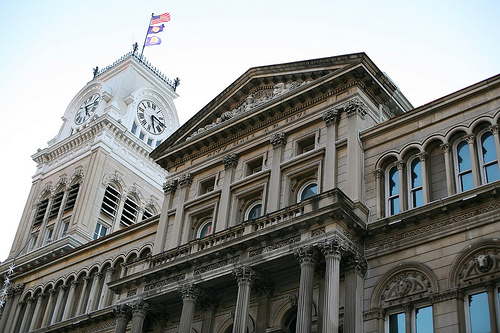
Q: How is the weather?
A: It is clear.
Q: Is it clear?
A: Yes, it is clear.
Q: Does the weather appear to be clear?
A: Yes, it is clear.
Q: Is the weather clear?
A: Yes, it is clear.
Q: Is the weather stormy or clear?
A: It is clear.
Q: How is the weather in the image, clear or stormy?
A: It is clear.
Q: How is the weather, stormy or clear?
A: It is clear.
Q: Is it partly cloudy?
A: No, it is clear.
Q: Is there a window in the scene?
A: Yes, there is a window.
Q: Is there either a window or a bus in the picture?
A: Yes, there is a window.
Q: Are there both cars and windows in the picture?
A: No, there is a window but no cars.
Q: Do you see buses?
A: No, there are no buses.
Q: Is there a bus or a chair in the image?
A: No, there are no buses or chairs.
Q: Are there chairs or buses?
A: No, there are no buses or chairs.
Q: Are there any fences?
A: No, there are no fences.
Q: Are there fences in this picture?
A: No, there are no fences.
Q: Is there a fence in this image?
A: No, there are no fences.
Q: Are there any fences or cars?
A: No, there are no fences or cars.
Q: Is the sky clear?
A: Yes, the sky is clear.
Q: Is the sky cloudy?
A: No, the sky is clear.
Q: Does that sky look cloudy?
A: No, the sky is clear.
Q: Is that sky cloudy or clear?
A: The sky is clear.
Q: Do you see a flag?
A: Yes, there is a flag.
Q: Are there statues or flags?
A: Yes, there is a flag.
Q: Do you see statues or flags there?
A: Yes, there is a flag.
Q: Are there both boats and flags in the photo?
A: No, there is a flag but no boats.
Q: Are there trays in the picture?
A: No, there are no trays.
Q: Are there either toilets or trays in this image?
A: No, there are no trays or toilets.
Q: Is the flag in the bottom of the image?
A: No, the flag is in the top of the image.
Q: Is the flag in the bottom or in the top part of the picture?
A: The flag is in the top of the image.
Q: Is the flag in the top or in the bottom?
A: The flag is in the top of the image.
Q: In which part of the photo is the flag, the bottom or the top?
A: The flag is in the top of the image.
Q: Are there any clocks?
A: Yes, there is a clock.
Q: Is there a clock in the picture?
A: Yes, there is a clock.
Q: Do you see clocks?
A: Yes, there is a clock.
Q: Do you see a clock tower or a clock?
A: Yes, there is a clock.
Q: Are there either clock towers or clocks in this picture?
A: Yes, there is a clock.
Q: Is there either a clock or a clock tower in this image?
A: Yes, there is a clock.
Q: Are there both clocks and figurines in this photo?
A: No, there is a clock but no figurines.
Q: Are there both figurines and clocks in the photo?
A: No, there is a clock but no figurines.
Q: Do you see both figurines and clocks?
A: No, there is a clock but no figurines.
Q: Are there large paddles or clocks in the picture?
A: Yes, there is a large clock.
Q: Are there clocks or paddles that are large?
A: Yes, the clock is large.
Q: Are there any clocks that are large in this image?
A: Yes, there is a large clock.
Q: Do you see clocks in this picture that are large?
A: Yes, there is a clock that is large.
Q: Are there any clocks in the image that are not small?
A: Yes, there is a large clock.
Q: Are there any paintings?
A: No, there are no paintings.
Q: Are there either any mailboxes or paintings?
A: No, there are no paintings or mailboxes.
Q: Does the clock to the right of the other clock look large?
A: Yes, the clock is large.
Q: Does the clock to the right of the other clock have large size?
A: Yes, the clock is large.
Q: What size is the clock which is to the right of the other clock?
A: The clock is large.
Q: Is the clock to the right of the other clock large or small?
A: The clock is large.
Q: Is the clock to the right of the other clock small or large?
A: The clock is large.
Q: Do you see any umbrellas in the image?
A: No, there are no umbrellas.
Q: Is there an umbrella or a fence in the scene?
A: No, there are no umbrellas or fences.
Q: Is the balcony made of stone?
A: Yes, the balcony is made of stone.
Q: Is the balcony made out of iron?
A: No, the balcony is made of stone.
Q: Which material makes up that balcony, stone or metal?
A: The balcony is made of stone.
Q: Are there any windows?
A: Yes, there is a window.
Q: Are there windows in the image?
A: Yes, there is a window.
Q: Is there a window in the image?
A: Yes, there is a window.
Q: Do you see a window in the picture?
A: Yes, there is a window.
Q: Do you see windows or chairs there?
A: Yes, there is a window.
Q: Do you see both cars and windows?
A: No, there is a window but no cars.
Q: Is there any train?
A: No, there are no trains.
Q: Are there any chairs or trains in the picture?
A: No, there are no trains or chairs.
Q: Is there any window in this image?
A: Yes, there is a window.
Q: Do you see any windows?
A: Yes, there is a window.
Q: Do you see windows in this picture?
A: Yes, there is a window.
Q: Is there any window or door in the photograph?
A: Yes, there is a window.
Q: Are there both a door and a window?
A: No, there is a window but no doors.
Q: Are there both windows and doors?
A: No, there is a window but no doors.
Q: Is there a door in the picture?
A: No, there are no doors.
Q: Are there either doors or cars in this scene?
A: No, there are no doors or cars.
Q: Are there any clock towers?
A: Yes, there is a clock tower.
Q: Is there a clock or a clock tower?
A: Yes, there is a clock tower.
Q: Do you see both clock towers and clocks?
A: Yes, there are both a clock tower and a clock.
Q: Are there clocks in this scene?
A: Yes, there is a clock.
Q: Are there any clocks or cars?
A: Yes, there is a clock.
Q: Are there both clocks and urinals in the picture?
A: No, there is a clock but no urinals.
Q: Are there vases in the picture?
A: No, there are no vases.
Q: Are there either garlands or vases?
A: No, there are no vases or garlands.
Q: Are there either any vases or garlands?
A: No, there are no vases or garlands.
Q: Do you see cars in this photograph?
A: No, there are no cars.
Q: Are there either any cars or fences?
A: No, there are no cars or fences.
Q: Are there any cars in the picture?
A: No, there are no cars.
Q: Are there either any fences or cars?
A: No, there are no cars or fences.